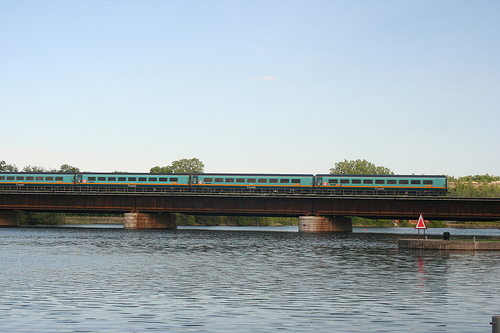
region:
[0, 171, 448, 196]
The train on the bridge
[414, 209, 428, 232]
The red triangular sign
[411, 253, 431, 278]
The red sign reflected on the water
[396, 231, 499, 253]
The cement platform the red sign is on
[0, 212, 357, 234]
The pillars holding up the bridge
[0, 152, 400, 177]
The trees seen behind the train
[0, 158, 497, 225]
The hill behind the bridge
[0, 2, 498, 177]
The sky above the hill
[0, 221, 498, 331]
The water passing under the bridge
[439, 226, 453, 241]
The black object next to the red sign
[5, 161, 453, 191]
Green train cars trimmed in bright orange.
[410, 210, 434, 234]
brightly colored triangular sign.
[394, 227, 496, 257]
Small pier in water.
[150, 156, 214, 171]
Treetop in background.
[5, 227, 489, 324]
Blue lake with many small waves.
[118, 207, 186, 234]
Left train track pedestal.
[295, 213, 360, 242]
Right train track pedestal.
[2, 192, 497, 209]
Black train track purched on the pedestals.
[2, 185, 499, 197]
Black train track railing.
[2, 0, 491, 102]
Bright blue sky.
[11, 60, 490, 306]
Train crossing a bridge.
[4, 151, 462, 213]
Four blue train cars.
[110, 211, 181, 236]
Concrete support for bridge on left side.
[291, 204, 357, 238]
Concrete support for bridge on right side.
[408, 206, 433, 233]
A triangle shaped sign.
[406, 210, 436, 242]
A red and white sign.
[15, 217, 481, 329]
A large body of water.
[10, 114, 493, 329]
Bridge crossing over water.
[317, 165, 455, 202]
Train car on right has nine windows.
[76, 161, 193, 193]
Train car on second from left has nine windows.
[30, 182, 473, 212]
Bridge over water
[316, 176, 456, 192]
Green and Orange train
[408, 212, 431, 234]
Red and white hazard sign in water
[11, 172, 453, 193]
Train on a bridge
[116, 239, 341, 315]
Blue water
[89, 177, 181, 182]
Window on a train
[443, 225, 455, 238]
Buoy in the middle of water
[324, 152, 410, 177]
Trees behind a train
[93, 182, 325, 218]
Metal frame on bridge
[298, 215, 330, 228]
Stone holding up a bridge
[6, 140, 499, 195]
train on railroad tracks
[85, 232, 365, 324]
river water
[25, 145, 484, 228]
train on a railroad bridge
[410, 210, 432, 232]
orange triangular sign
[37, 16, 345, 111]
blue sky that may be somewhat cloudy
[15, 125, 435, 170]
leaves against the sky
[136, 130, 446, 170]
trees against a blue sky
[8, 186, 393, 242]
bridge for a train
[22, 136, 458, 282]
train traveling over water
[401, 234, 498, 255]
concrete platform by railroad tracks